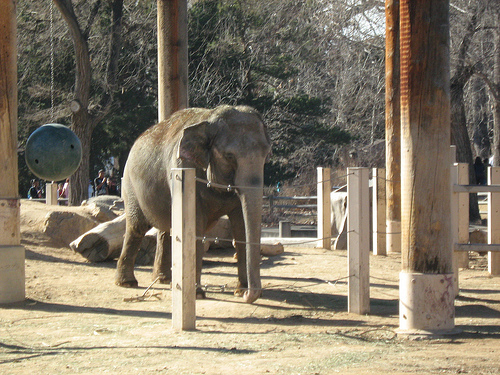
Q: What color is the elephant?
A: Gray.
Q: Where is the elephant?
A: On the dirt.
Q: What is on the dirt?
A: The elephant.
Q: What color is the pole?
A: Brown.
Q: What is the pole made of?
A: Wood.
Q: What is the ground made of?
A: Dirt.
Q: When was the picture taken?
A: Daytime.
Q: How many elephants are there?
A: One.